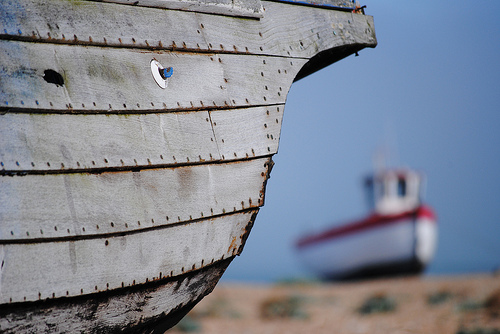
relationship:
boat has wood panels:
[12, 16, 293, 332] [17, 35, 268, 330]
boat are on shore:
[0, 0, 377, 332] [225, 281, 487, 318]